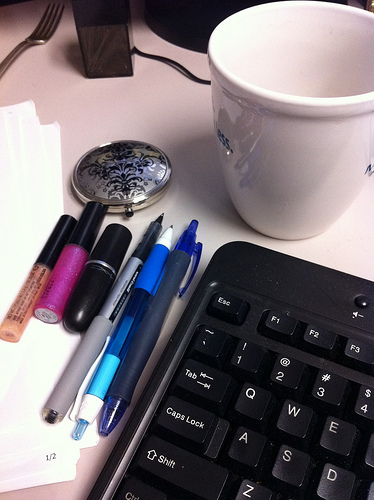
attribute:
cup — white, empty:
[206, 0, 373, 240]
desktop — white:
[1, 0, 373, 500]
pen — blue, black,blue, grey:
[68, 224, 173, 442]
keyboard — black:
[86, 242, 373, 500]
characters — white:
[124, 296, 370, 500]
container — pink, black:
[34, 200, 109, 324]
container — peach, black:
[1, 215, 79, 342]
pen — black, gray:
[42, 213, 163, 424]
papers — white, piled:
[1, 99, 99, 494]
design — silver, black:
[77, 142, 167, 200]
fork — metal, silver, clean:
[1, 0, 65, 78]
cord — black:
[134, 46, 211, 85]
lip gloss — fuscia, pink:
[33, 244, 88, 323]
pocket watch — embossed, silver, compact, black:
[72, 139, 170, 218]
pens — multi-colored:
[43, 211, 202, 439]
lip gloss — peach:
[1, 215, 78, 343]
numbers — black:
[44, 452, 57, 462]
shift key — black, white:
[130, 433, 232, 499]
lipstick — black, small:
[62, 224, 132, 333]